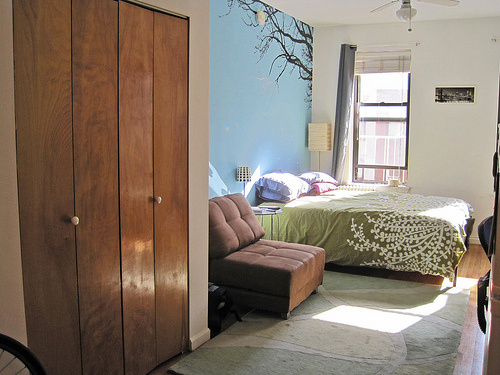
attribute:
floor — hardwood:
[455, 236, 490, 290]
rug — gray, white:
[165, 269, 479, 372]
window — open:
[356, 70, 409, 167]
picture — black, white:
[431, 84, 475, 104]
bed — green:
[247, 168, 473, 286]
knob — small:
[146, 192, 167, 209]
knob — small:
[64, 209, 86, 230]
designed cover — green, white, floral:
[322, 177, 459, 258]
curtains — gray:
[332, 45, 354, 180]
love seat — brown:
[207, 192, 324, 314]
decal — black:
[214, 2, 317, 129]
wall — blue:
[204, 1, 335, 220]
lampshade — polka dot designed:
[229, 164, 257, 187]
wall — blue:
[203, 1, 335, 255]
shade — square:
[306, 117, 339, 154]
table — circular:
[235, 201, 285, 249]